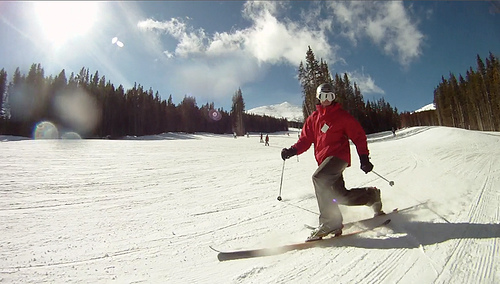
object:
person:
[392, 127, 396, 137]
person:
[265, 134, 270, 146]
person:
[260, 132, 264, 142]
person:
[247, 132, 250, 138]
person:
[233, 132, 237, 139]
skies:
[0, 0, 449, 44]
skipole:
[277, 160, 285, 201]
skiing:
[208, 205, 401, 254]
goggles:
[317, 92, 335, 102]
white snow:
[28, 152, 127, 226]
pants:
[312, 156, 372, 229]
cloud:
[137, 0, 433, 95]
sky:
[1, 0, 491, 115]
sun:
[31, 0, 103, 42]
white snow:
[53, 216, 255, 284]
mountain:
[410, 103, 437, 115]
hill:
[245, 101, 305, 122]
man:
[281, 83, 382, 242]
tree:
[231, 86, 245, 136]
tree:
[123, 82, 157, 136]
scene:
[3, 1, 500, 281]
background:
[0, 0, 499, 132]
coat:
[291, 102, 370, 167]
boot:
[365, 187, 382, 216]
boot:
[305, 223, 343, 242]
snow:
[0, 126, 500, 284]